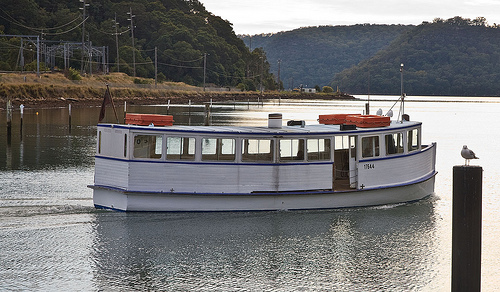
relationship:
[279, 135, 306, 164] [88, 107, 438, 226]
window on ship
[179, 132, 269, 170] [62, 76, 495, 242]
window on ship